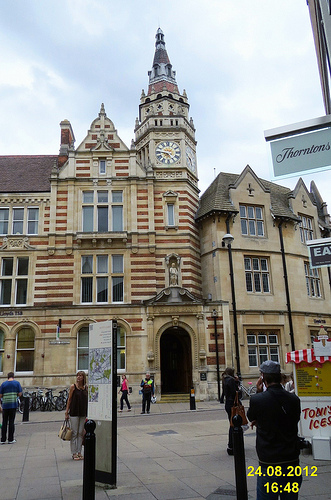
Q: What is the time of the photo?
A: 16:48.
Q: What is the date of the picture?
A: 24.08.2012.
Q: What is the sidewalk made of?
A: Cement.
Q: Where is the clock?
A: On the tower.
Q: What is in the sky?
A: Clouds.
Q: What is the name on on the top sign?
A: Thorntons.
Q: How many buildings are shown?
A: Two.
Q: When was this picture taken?
A: Day time.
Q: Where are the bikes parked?
A: By the buildings.